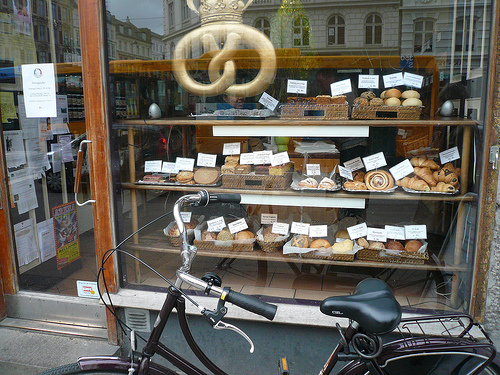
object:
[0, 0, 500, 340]
bakery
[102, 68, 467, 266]
sale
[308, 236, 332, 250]
pastry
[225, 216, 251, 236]
display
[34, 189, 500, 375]
bicycle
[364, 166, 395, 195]
rolls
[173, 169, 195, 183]
goods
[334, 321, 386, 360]
cable lock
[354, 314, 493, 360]
luggage rack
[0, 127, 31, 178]
posters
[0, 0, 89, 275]
wall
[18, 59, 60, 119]
sign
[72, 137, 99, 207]
handle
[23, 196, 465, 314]
tile floor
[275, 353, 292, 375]
bike pedal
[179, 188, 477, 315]
reflective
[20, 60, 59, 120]
paper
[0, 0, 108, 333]
door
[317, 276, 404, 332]
seat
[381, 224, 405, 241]
display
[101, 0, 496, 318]
window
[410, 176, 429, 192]
croissant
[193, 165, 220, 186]
bread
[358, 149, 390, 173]
paper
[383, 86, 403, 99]
bread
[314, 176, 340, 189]
bread